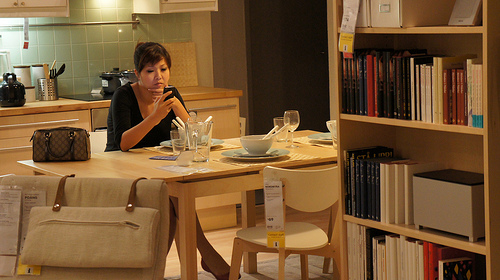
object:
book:
[428, 246, 441, 280]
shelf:
[345, 216, 483, 278]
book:
[470, 64, 478, 131]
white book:
[419, 65, 430, 123]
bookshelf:
[327, 0, 500, 280]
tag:
[335, 24, 357, 59]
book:
[382, 236, 399, 278]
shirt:
[102, 82, 191, 154]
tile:
[83, 19, 110, 50]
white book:
[392, 162, 401, 227]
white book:
[377, 164, 387, 220]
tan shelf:
[322, 0, 498, 277]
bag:
[30, 126, 95, 162]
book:
[425, 66, 432, 121]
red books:
[367, 55, 374, 116]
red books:
[452, 69, 457, 124]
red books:
[430, 246, 439, 280]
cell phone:
[163, 85, 176, 104]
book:
[344, 150, 348, 214]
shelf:
[339, 110, 486, 136]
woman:
[97, 39, 214, 154]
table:
[13, 120, 367, 242]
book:
[380, 162, 392, 230]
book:
[361, 52, 377, 116]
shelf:
[331, 23, 495, 133]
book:
[422, 239, 429, 277]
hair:
[134, 41, 173, 74]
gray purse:
[29, 125, 92, 163]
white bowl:
[240, 132, 273, 153]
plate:
[219, 147, 289, 161]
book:
[409, 57, 416, 119]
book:
[415, 64, 421, 120]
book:
[464, 56, 471, 125]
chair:
[225, 165, 338, 280]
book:
[380, 163, 386, 222]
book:
[386, 163, 391, 224]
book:
[392, 161, 402, 225]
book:
[404, 164, 412, 225]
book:
[422, 64, 425, 122]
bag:
[20, 175, 160, 270]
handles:
[51, 174, 75, 212]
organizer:
[21, 174, 158, 268]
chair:
[0, 173, 169, 278]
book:
[436, 259, 483, 280]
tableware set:
[140, 109, 335, 167]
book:
[415, 63, 420, 120]